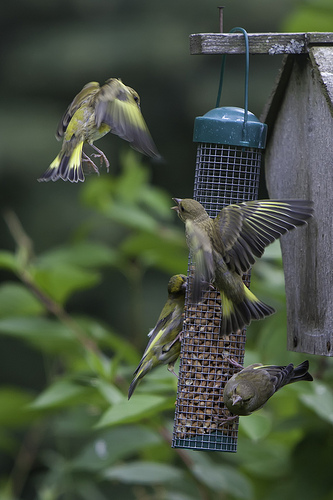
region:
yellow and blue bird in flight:
[37, 78, 164, 187]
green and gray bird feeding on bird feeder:
[220, 354, 332, 418]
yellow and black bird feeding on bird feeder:
[125, 271, 193, 398]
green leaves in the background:
[0, 142, 326, 494]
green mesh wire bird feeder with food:
[170, 23, 265, 461]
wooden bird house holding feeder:
[190, 21, 330, 361]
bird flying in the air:
[40, 66, 156, 187]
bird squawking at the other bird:
[167, 187, 318, 334]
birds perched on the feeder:
[115, 270, 312, 425]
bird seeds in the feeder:
[167, 259, 256, 438]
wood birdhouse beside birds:
[188, 35, 332, 355]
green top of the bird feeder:
[188, 25, 267, 143]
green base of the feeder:
[173, 429, 234, 453]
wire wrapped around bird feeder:
[165, 143, 254, 451]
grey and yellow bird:
[127, 274, 195, 386]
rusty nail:
[215, 4, 228, 29]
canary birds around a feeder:
[37, 64, 304, 456]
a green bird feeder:
[161, 95, 245, 440]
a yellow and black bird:
[208, 344, 327, 462]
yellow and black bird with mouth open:
[157, 172, 312, 358]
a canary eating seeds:
[113, 246, 212, 430]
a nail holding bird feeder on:
[180, 5, 287, 61]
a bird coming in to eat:
[34, 50, 176, 244]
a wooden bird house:
[209, 30, 331, 365]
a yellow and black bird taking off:
[168, 169, 319, 356]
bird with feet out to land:
[25, 71, 192, 224]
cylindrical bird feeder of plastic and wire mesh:
[168, 21, 270, 452]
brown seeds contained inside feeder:
[171, 275, 247, 451]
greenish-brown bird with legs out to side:
[213, 353, 314, 432]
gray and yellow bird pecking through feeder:
[124, 272, 192, 399]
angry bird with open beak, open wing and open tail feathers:
[164, 191, 314, 336]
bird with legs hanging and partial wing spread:
[32, 72, 161, 187]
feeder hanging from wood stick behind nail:
[186, 1, 263, 165]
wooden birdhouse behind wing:
[251, 27, 326, 356]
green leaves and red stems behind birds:
[9, 72, 325, 485]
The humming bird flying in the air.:
[44, 79, 164, 184]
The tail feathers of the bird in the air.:
[40, 147, 85, 186]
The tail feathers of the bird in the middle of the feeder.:
[216, 278, 274, 332]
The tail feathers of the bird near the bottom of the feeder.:
[268, 361, 314, 384]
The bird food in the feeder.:
[174, 269, 242, 435]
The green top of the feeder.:
[193, 106, 268, 147]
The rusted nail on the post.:
[216, 3, 225, 34]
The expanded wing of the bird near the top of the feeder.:
[214, 192, 308, 255]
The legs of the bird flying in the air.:
[82, 141, 110, 174]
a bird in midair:
[37, 62, 170, 202]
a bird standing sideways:
[203, 356, 315, 428]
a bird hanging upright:
[117, 268, 198, 409]